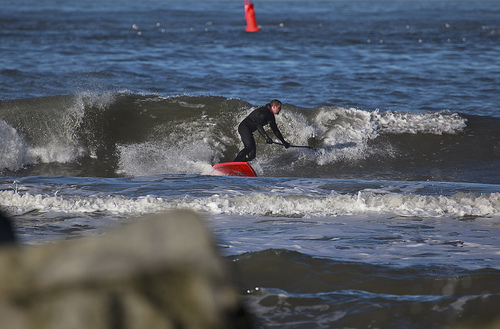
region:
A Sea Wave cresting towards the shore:
[0, 88, 210, 176]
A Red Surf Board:
[204, 156, 271, 178]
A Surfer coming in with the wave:
[197, 99, 298, 179]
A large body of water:
[303, 9, 496, 84]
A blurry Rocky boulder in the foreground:
[0, 200, 250, 327]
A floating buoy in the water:
[223, 0, 269, 33]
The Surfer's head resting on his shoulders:
[265, 93, 288, 120]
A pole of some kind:
[262, 136, 314, 152]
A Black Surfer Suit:
[228, 107, 295, 162]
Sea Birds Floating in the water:
[125, 18, 145, 37]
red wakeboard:
[198, 150, 285, 215]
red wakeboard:
[185, 135, 262, 190]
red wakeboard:
[182, 97, 270, 224]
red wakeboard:
[171, 128, 291, 173]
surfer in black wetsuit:
[215, 97, 289, 179]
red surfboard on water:
[212, 156, 261, 183]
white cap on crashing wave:
[353, 110, 430, 137]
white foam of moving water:
[288, 188, 394, 218]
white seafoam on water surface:
[348, 226, 432, 263]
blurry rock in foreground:
[56, 211, 223, 318]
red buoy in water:
[234, 3, 268, 43]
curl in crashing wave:
[67, 86, 141, 162]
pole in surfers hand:
[262, 133, 320, 155]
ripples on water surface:
[313, 41, 410, 89]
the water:
[256, 173, 353, 245]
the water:
[333, 230, 378, 320]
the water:
[311, 184, 339, 311]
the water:
[293, 158, 329, 316]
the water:
[333, 180, 358, 303]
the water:
[289, 224, 330, 304]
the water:
[326, 240, 348, 308]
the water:
[319, 214, 336, 308]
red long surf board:
[208, 148, 264, 186]